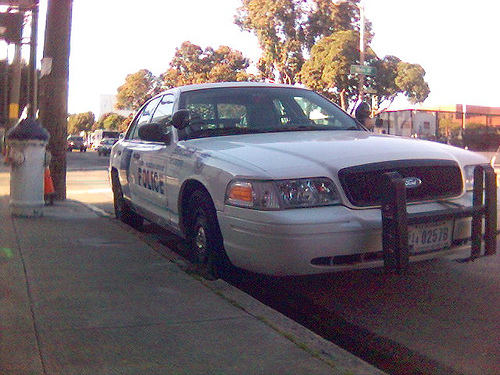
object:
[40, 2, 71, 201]
brown pole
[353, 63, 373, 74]
street sign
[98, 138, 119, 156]
cars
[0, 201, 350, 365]
cement sidewalk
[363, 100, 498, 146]
white building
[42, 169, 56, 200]
pylon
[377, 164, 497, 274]
batting ram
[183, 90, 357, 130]
caged enclosure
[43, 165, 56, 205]
cone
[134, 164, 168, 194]
lettering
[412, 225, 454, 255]
license plate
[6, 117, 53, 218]
fire hydrant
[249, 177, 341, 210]
headlight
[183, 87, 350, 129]
windshield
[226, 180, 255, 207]
right blinker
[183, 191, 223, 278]
front tire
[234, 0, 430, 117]
tree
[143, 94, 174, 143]
side window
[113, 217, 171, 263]
curbside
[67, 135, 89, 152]
cars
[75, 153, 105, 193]
road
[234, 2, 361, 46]
tree tops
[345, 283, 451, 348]
street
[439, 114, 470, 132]
fence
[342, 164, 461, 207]
car grill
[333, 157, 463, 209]
cage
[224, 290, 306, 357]
curb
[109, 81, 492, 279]
car